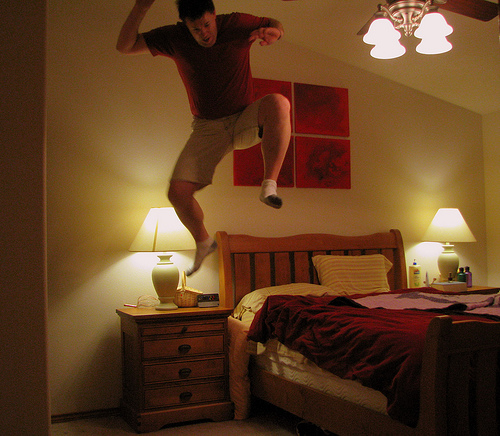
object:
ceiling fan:
[356, 0, 500, 37]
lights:
[413, 12, 453, 56]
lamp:
[422, 205, 476, 294]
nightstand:
[431, 281, 500, 301]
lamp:
[128, 204, 198, 310]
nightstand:
[113, 297, 233, 432]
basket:
[173, 269, 203, 310]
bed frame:
[215, 227, 498, 434]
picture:
[293, 135, 352, 191]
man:
[114, 1, 292, 277]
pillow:
[307, 253, 393, 295]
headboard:
[214, 229, 405, 308]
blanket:
[353, 287, 498, 311]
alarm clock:
[194, 292, 222, 309]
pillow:
[239, 275, 338, 313]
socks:
[182, 230, 220, 278]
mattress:
[234, 289, 500, 414]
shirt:
[138, 12, 273, 121]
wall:
[44, 0, 481, 419]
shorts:
[167, 93, 263, 188]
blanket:
[246, 291, 499, 434]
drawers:
[138, 319, 224, 413]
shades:
[420, 206, 477, 244]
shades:
[128, 206, 198, 252]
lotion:
[407, 258, 420, 287]